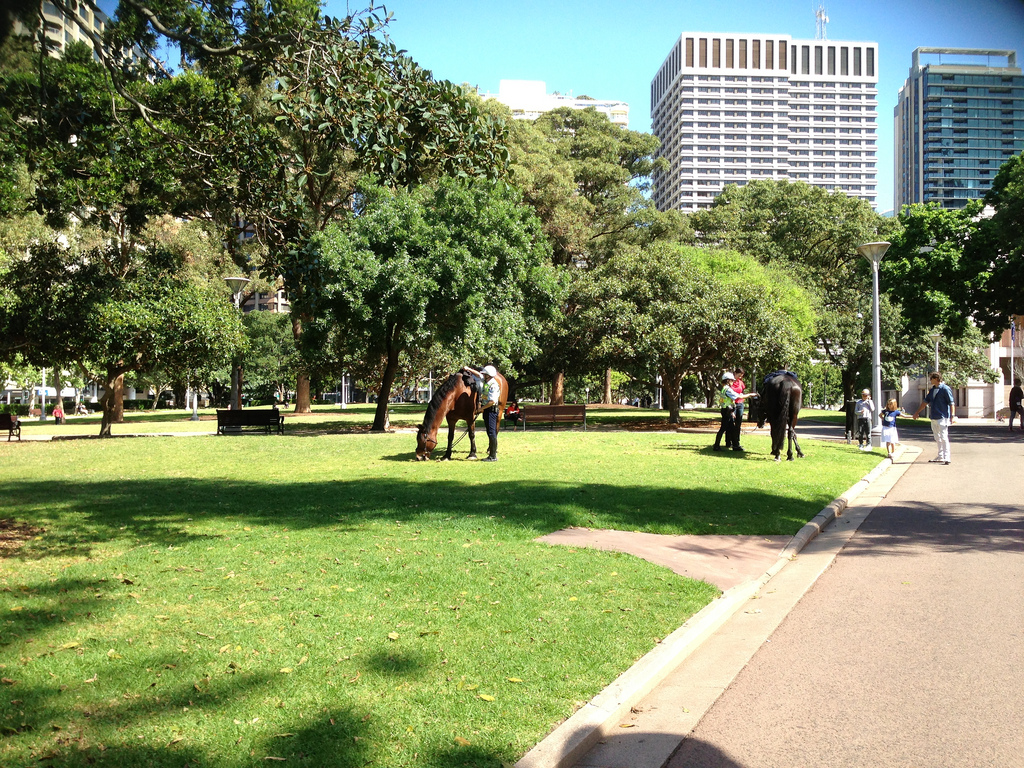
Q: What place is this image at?
A: It is at the park.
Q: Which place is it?
A: It is a park.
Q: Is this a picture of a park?
A: Yes, it is showing a park.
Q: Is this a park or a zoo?
A: It is a park.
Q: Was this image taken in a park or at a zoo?
A: It was taken at a park.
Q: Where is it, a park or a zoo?
A: It is a park.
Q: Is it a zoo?
A: No, it is a park.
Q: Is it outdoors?
A: Yes, it is outdoors.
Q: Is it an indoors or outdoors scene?
A: It is outdoors.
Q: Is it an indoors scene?
A: No, it is outdoors.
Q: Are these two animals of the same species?
A: Yes, all the animals are horses.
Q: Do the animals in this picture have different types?
A: No, all the animals are horses.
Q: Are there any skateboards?
A: No, there are no skateboards.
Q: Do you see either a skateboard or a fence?
A: No, there are no skateboards or fences.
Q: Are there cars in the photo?
A: No, there are no cars.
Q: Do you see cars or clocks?
A: No, there are no cars or clocks.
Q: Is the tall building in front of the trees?
A: No, the building is behind the trees.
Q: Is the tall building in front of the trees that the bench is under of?
A: No, the building is behind the trees.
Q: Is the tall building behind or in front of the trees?
A: The building is behind the trees.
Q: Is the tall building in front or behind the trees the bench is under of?
A: The building is behind the trees.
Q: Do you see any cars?
A: No, there are no cars.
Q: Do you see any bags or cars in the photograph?
A: No, there are no cars or bags.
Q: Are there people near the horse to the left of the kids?
A: Yes, there are people near the horse.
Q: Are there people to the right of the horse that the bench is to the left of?
A: Yes, there are people to the right of the horse.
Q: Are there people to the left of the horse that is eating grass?
A: No, the people are to the right of the horse.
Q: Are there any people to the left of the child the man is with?
A: Yes, there are people to the left of the kid.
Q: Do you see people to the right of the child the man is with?
A: No, the people are to the left of the kid.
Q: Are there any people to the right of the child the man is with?
A: No, the people are to the left of the kid.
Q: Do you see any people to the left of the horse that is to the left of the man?
A: Yes, there are people to the left of the horse.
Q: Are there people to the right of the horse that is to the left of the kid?
A: No, the people are to the left of the horse.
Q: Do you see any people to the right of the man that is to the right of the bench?
A: Yes, there are people to the right of the man.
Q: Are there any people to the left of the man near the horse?
A: No, the people are to the right of the man.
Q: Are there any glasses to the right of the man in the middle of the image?
A: No, there are people to the right of the man.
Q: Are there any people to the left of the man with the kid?
A: Yes, there are people to the left of the man.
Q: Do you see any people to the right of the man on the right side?
A: No, the people are to the left of the man.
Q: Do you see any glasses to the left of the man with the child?
A: No, there are people to the left of the man.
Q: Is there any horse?
A: Yes, there is a horse.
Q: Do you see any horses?
A: Yes, there is a horse.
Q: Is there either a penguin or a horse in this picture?
A: Yes, there is a horse.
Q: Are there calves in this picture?
A: No, there are no calves.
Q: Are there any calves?
A: No, there are no calves.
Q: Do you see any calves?
A: No, there are no calves.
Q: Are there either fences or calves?
A: No, there are no calves or fences.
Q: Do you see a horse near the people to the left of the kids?
A: Yes, there is a horse near the people.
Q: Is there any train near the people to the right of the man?
A: No, there is a horse near the people.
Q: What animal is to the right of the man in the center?
A: The animal is a horse.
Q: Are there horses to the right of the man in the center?
A: Yes, there is a horse to the right of the man.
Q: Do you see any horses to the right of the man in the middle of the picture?
A: Yes, there is a horse to the right of the man.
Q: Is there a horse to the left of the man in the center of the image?
A: No, the horse is to the right of the man.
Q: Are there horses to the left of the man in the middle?
A: No, the horse is to the right of the man.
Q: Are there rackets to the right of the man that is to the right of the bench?
A: No, there is a horse to the right of the man.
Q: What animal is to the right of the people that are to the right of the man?
A: The animal is a horse.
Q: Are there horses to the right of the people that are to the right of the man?
A: Yes, there is a horse to the right of the people.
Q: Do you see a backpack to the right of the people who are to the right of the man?
A: No, there is a horse to the right of the people.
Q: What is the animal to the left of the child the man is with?
A: The animal is a horse.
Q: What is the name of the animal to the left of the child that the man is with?
A: The animal is a horse.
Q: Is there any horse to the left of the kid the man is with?
A: Yes, there is a horse to the left of the kid.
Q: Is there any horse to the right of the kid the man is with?
A: No, the horse is to the left of the child.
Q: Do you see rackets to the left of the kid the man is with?
A: No, there is a horse to the left of the child.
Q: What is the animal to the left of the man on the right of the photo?
A: The animal is a horse.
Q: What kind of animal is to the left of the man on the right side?
A: The animal is a horse.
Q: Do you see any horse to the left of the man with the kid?
A: Yes, there is a horse to the left of the man.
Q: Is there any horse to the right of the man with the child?
A: No, the horse is to the left of the man.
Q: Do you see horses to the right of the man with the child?
A: No, the horse is to the left of the man.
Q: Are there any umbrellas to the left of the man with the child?
A: No, there is a horse to the left of the man.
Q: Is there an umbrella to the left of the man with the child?
A: No, there is a horse to the left of the man.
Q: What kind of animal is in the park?
A: The animal is a horse.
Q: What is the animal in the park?
A: The animal is a horse.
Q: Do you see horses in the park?
A: Yes, there is a horse in the park.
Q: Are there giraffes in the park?
A: No, there is a horse in the park.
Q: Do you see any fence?
A: No, there are no fences.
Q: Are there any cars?
A: No, there are no cars.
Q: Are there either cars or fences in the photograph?
A: No, there are no cars or fences.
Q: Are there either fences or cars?
A: No, there are no cars or fences.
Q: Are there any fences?
A: No, there are no fences.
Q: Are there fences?
A: No, there are no fences.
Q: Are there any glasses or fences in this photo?
A: No, there are no fences or glasses.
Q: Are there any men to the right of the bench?
A: Yes, there is a man to the right of the bench.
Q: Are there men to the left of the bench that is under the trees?
A: No, the man is to the right of the bench.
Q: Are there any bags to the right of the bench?
A: No, there is a man to the right of the bench.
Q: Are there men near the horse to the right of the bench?
A: Yes, there is a man near the horse.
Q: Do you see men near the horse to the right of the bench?
A: Yes, there is a man near the horse.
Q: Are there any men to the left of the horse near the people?
A: Yes, there is a man to the left of the horse.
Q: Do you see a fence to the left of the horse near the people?
A: No, there is a man to the left of the horse.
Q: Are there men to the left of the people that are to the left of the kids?
A: Yes, there is a man to the left of the people.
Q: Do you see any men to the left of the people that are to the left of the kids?
A: Yes, there is a man to the left of the people.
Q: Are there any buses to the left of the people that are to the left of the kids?
A: No, there is a man to the left of the people.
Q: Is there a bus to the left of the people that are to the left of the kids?
A: No, there is a man to the left of the people.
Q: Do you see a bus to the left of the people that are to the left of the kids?
A: No, there is a man to the left of the people.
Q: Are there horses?
A: Yes, there is a horse.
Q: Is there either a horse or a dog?
A: Yes, there is a horse.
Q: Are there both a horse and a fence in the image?
A: No, there is a horse but no fences.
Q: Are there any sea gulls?
A: No, there are no sea gulls.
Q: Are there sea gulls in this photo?
A: No, there are no sea gulls.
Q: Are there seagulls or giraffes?
A: No, there are no seagulls or giraffes.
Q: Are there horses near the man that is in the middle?
A: Yes, there is a horse near the man.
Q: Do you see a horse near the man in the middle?
A: Yes, there is a horse near the man.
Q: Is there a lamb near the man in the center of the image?
A: No, there is a horse near the man.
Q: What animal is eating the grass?
A: The horse is eating the grass.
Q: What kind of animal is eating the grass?
A: The animal is a horse.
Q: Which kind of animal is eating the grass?
A: The animal is a horse.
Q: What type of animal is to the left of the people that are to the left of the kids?
A: The animal is a horse.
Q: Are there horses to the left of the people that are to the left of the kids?
A: Yes, there is a horse to the left of the people.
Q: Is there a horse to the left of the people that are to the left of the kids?
A: Yes, there is a horse to the left of the people.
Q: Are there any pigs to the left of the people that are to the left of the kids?
A: No, there is a horse to the left of the people.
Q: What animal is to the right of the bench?
A: The animal is a horse.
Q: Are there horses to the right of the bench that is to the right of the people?
A: Yes, there is a horse to the right of the bench.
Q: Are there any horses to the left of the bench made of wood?
A: No, the horse is to the right of the bench.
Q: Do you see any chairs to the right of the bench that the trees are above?
A: No, there is a horse to the right of the bench.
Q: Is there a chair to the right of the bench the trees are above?
A: No, there is a horse to the right of the bench.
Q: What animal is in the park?
A: The animal is a horse.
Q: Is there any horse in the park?
A: Yes, there is a horse in the park.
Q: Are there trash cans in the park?
A: No, there is a horse in the park.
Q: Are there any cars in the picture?
A: No, there are no cars.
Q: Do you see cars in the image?
A: No, there are no cars.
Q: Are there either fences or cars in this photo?
A: No, there are no cars or fences.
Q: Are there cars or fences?
A: No, there are no cars or fences.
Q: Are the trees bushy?
A: Yes, the trees are bushy.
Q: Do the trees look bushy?
A: Yes, the trees are bushy.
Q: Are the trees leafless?
A: No, the trees are bushy.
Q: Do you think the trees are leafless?
A: No, the trees are bushy.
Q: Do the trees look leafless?
A: No, the trees are bushy.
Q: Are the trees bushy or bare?
A: The trees are bushy.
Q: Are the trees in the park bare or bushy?
A: The trees are bushy.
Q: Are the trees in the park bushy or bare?
A: The trees are bushy.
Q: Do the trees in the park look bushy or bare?
A: The trees are bushy.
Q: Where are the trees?
A: The trees are in the park.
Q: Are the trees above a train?
A: No, the trees are above the bench.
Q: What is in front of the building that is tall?
A: The trees are in front of the building.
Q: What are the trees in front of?
A: The trees are in front of the building.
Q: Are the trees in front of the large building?
A: Yes, the trees are in front of the building.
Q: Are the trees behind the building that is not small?
A: No, the trees are in front of the building.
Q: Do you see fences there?
A: No, there are no fences.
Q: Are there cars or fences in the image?
A: No, there are no fences or cars.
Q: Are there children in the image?
A: Yes, there is a child.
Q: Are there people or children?
A: Yes, there is a child.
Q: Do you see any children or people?
A: Yes, there is a child.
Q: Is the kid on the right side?
A: Yes, the kid is on the right of the image.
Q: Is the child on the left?
A: No, the child is on the right of the image.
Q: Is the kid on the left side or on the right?
A: The kid is on the right of the image.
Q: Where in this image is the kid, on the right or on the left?
A: The kid is on the right of the image.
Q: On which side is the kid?
A: The kid is on the right of the image.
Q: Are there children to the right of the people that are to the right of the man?
A: Yes, there is a child to the right of the people.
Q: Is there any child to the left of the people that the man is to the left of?
A: No, the child is to the right of the people.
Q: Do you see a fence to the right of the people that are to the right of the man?
A: No, there is a child to the right of the people.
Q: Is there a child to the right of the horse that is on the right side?
A: Yes, there is a child to the right of the horse.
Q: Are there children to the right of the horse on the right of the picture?
A: Yes, there is a child to the right of the horse.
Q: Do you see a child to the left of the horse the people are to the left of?
A: No, the child is to the right of the horse.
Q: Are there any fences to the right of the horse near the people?
A: No, there is a child to the right of the horse.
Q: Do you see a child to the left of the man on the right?
A: Yes, there is a child to the left of the man.